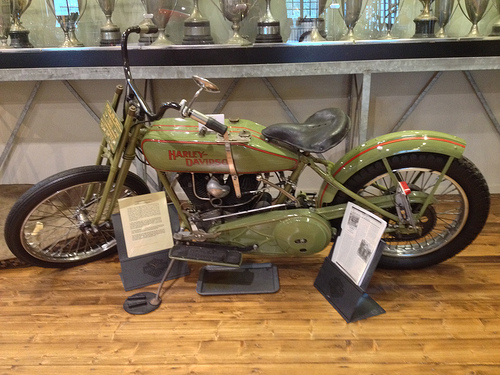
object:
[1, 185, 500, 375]
floor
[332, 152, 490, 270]
wheel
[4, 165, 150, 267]
wheel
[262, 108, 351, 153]
seat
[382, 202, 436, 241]
gear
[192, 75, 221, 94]
mirror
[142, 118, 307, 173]
tank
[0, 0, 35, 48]
trophies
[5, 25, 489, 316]
motorcycle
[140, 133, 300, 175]
stripe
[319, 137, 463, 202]
stripe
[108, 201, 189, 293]
document holder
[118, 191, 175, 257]
paper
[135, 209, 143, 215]
words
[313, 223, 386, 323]
document holder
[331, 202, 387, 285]
paper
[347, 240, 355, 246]
words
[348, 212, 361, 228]
photo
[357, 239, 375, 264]
photo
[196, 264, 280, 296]
tray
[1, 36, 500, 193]
table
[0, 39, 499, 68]
stripe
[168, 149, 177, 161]
words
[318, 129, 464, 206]
fender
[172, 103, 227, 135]
handle bars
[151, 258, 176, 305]
kickstand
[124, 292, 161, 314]
mat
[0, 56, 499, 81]
bar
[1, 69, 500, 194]
wall